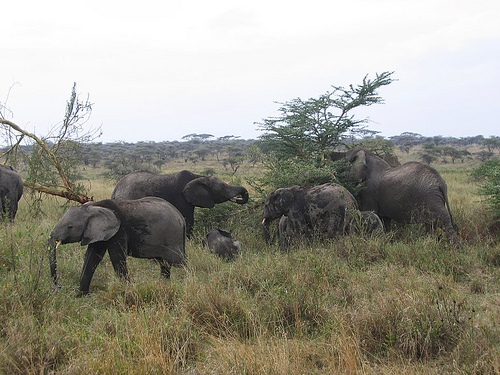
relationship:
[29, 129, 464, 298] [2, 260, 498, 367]
elephants in tall grass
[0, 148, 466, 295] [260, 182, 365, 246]
area with elephants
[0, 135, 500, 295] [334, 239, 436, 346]
area of grass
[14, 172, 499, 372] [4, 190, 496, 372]
grass in field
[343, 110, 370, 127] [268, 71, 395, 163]
tree branch with green foliage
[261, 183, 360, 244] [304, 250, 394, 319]
elephant in grass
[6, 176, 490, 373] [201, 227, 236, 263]
plain with elephant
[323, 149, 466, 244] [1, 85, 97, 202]
elephant under tree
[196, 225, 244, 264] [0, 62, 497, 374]
elephant in vegetation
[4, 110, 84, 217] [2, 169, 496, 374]
tree fallen to ground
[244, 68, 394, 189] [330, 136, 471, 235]
tree behind elephant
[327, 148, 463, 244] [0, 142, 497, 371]
elephant grazing in field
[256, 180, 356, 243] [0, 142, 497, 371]
elephant grazing in field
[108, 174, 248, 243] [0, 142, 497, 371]
elephant grazing in field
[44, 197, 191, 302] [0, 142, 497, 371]
elephant grazing in field